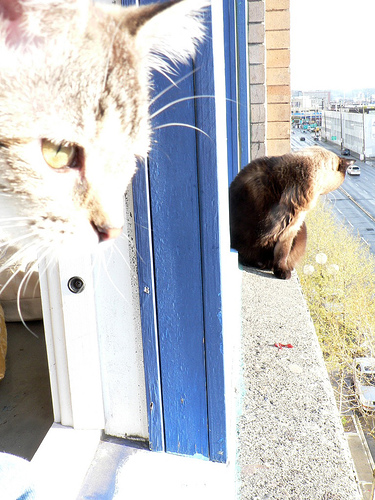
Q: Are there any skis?
A: No, there are no skis.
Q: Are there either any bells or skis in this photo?
A: No, there are no skis or bells.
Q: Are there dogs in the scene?
A: No, there are no dogs.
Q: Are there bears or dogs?
A: No, there are no dogs or bears.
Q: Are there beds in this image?
A: No, there are no beds.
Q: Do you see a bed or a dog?
A: No, there are no beds or dogs.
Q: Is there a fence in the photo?
A: No, there are no fences.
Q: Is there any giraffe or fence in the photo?
A: No, there are no fences or giraffes.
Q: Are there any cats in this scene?
A: Yes, there is a cat.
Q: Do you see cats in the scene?
A: Yes, there is a cat.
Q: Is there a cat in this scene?
A: Yes, there is a cat.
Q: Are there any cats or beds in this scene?
A: Yes, there is a cat.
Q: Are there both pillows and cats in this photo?
A: No, there is a cat but no pillows.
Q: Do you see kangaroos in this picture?
A: No, there are no kangaroos.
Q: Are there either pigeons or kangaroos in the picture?
A: No, there are no kangaroos or pigeons.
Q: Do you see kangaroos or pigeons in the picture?
A: No, there are no kangaroos or pigeons.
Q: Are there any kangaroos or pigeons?
A: No, there are no kangaroos or pigeons.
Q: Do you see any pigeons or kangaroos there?
A: No, there are no kangaroos or pigeons.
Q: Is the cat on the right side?
A: Yes, the cat is on the right of the image.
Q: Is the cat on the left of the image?
A: No, the cat is on the right of the image.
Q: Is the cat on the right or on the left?
A: The cat is on the right of the image.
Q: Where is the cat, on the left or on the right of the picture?
A: The cat is on the right of the image.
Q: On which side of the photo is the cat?
A: The cat is on the right of the image.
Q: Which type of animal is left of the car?
A: The animal is a cat.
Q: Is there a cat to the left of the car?
A: Yes, there is a cat to the left of the car.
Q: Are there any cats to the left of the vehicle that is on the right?
A: Yes, there is a cat to the left of the car.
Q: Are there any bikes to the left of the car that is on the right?
A: No, there is a cat to the left of the car.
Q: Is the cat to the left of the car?
A: Yes, the cat is to the left of the car.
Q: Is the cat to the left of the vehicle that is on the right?
A: Yes, the cat is to the left of the car.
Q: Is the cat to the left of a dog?
A: No, the cat is to the left of the car.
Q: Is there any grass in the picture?
A: Yes, there is grass.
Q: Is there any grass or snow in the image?
A: Yes, there is grass.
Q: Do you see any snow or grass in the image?
A: Yes, there is grass.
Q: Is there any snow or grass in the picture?
A: Yes, there is grass.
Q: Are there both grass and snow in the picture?
A: No, there is grass but no snow.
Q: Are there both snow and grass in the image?
A: No, there is grass but no snow.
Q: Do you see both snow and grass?
A: No, there is grass but no snow.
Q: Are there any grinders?
A: No, there are no grinders.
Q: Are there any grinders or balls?
A: No, there are no grinders or balls.